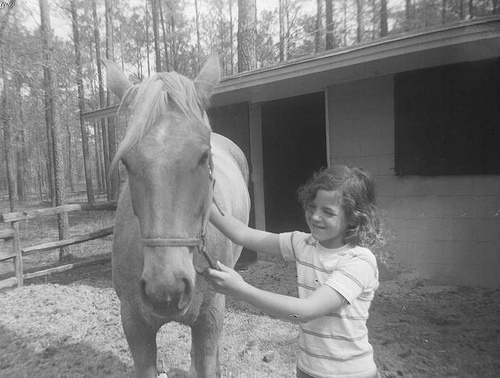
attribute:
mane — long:
[91, 45, 215, 170]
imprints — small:
[86, 286, 121, 339]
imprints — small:
[243, 324, 268, 360]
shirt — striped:
[284, 241, 372, 373]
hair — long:
[100, 66, 205, 158]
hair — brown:
[348, 176, 380, 248]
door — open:
[260, 111, 322, 218]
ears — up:
[94, 47, 225, 103]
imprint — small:
[253, 337, 276, 352]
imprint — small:
[82, 325, 98, 338]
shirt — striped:
[275, 216, 371, 370]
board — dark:
[387, 59, 499, 187]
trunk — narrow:
[43, 1, 73, 268]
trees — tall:
[38, 3, 80, 258]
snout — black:
[140, 276, 192, 311]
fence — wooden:
[2, 197, 120, 287]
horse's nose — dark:
[136, 273, 199, 321]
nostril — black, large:
[169, 264, 197, 305]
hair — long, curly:
[296, 161, 391, 270]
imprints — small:
[7, 314, 116, 375]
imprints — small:
[431, 294, 488, 357]